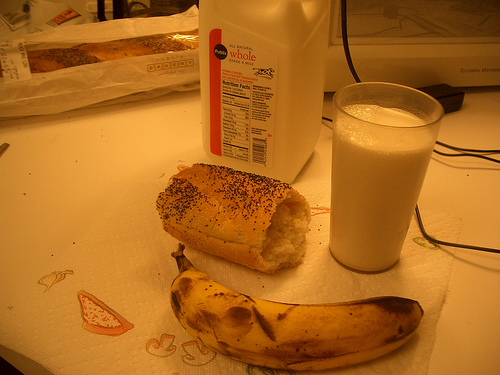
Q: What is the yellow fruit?
A: Banana.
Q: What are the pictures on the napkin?
A: Food.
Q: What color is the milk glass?
A: Clear.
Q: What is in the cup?
A: Milk.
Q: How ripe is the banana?
A: Very ripe.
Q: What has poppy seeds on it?
A: Bread.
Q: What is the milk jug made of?
A: Plastic.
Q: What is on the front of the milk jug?
A: Label.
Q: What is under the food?
A: Napkin.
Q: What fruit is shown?
A: A banana.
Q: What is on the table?
A: Banana.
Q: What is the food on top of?
A: Table.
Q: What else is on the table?
A: Chunk of bread.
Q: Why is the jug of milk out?
A: To pour into glass.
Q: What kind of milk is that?
A: Whole milk.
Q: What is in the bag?
A: Loaf of bread.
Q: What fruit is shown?
A: Banana.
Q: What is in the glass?
A: Milk.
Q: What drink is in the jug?
A: Milk.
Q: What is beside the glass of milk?
A: Bread.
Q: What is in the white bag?
A: Bread.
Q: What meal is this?
A: Lunch,.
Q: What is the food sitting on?
A: Paper towel.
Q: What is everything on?
A: Table.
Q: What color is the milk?
A: White.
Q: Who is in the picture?
A: No one.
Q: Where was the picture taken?
A: On a counter.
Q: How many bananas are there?
A: 1.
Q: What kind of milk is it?
A: Whole.